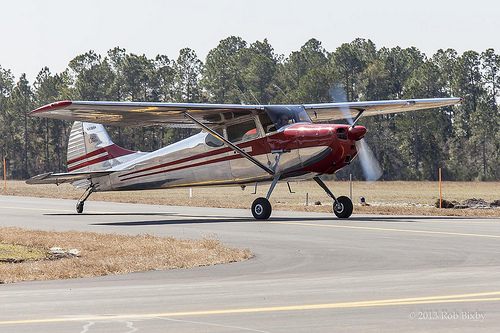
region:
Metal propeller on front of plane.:
[333, 91, 388, 181]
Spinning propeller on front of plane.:
[330, 91, 388, 181]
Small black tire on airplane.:
[248, 197, 273, 217]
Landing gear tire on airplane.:
[251, 198, 270, 217]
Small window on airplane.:
[225, 120, 260, 145]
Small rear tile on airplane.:
[74, 201, 85, 211]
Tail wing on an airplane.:
[63, 119, 128, 173]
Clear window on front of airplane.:
[221, 121, 262, 141]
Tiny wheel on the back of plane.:
[75, 200, 85, 210]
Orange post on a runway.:
[436, 167, 444, 209]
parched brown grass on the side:
[85, 236, 159, 263]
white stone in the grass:
[38, 234, 110, 259]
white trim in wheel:
[253, 196, 269, 221]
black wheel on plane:
[225, 186, 282, 218]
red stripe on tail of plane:
[61, 149, 133, 169]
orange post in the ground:
[430, 166, 447, 220]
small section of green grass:
[10, 233, 40, 263]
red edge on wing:
[15, 90, 99, 135]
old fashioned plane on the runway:
[43, 57, 450, 209]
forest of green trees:
[153, 45, 385, 94]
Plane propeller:
[297, 86, 411, 188]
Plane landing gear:
[236, 154, 366, 228]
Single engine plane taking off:
[12, 71, 493, 224]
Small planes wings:
[17, 89, 476, 127]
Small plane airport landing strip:
[0, 192, 497, 313]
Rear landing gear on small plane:
[67, 187, 117, 217]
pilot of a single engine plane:
[270, 106, 295, 131]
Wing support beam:
[175, 106, 287, 178]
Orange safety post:
[430, 162, 455, 211]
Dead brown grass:
[4, 225, 227, 277]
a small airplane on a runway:
[1, 2, 499, 322]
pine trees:
[459, 38, 498, 212]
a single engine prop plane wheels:
[236, 170, 368, 236]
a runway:
[21, 223, 488, 322]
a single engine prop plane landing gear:
[240, 165, 370, 245]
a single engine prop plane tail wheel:
[60, 176, 106, 217]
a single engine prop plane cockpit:
[187, 101, 312, 146]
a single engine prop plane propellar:
[322, 62, 397, 197]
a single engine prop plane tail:
[36, 91, 137, 228]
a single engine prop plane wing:
[28, 70, 478, 135]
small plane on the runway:
[21, 82, 468, 241]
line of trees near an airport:
[0, 31, 498, 200]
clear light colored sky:
[0, 0, 499, 94]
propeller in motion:
[329, 77, 384, 188]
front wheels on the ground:
[246, 189, 359, 223]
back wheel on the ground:
[70, 192, 92, 216]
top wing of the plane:
[24, 84, 471, 119]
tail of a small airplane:
[56, 110, 147, 172]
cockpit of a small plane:
[207, 103, 317, 140]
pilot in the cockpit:
[273, 109, 293, 131]